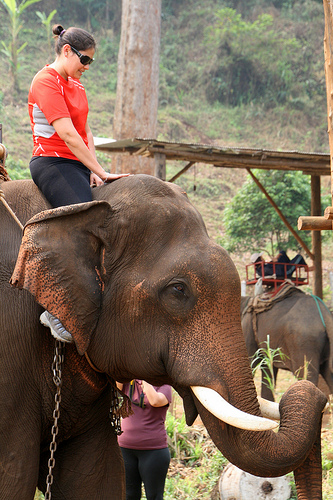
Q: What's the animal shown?
A: Elephant.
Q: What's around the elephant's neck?
A: Chain.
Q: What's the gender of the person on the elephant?
A: Female.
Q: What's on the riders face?
A: Sunglasses.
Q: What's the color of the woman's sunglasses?
A: Black.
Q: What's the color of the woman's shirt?
A: Red.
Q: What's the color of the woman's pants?
A: Black.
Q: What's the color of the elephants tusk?
A: White.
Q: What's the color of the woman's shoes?
A: Gray and white.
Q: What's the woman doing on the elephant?
A: Riding.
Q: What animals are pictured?
A: Elephants.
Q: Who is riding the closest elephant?
A: A woman wearing red.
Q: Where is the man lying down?
A: In a basket.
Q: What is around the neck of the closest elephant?
A: A chain.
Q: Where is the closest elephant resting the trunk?
A: On the left tusk.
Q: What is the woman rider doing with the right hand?
A: Patting the elephant.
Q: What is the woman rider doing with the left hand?
A: Holding on to a rope.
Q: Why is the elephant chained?
A: To control it.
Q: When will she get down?
A: When the ride is over.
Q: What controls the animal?
A: A handler.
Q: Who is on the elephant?
A: A woman.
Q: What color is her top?
A: Red with gray.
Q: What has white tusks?
A: The elephant.